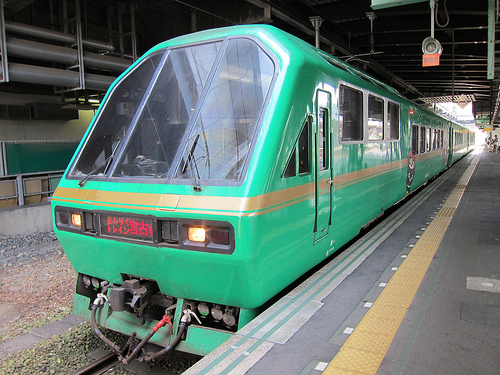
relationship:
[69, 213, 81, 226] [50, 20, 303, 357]
headlight on front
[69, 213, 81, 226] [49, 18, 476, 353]
headlight on train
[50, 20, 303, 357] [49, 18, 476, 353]
front of train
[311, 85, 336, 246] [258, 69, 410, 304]
door on side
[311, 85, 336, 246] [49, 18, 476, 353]
door on train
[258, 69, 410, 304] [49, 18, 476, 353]
side of train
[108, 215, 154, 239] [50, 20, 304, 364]
letters on front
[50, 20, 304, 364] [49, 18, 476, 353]
front of train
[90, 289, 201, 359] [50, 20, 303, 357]
wires on front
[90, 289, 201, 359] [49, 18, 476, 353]
wires on train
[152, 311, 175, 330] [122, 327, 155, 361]
grip on tube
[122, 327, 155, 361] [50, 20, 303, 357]
tube on front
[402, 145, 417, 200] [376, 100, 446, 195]
design on side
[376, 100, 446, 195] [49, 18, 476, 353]
side of train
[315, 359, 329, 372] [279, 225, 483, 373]
square on platform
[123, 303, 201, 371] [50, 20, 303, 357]
hoses on front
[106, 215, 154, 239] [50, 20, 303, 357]
letters on front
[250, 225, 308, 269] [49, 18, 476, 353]
green color on train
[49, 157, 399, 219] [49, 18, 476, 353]
border around train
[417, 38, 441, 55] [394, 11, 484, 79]
flood light in ceiling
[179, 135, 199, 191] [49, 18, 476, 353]
wiper on train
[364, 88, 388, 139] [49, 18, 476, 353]
window on train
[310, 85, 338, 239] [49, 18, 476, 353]
door on train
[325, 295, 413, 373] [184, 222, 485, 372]
line on ground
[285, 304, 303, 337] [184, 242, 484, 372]
stripe on ground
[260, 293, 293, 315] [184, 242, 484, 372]
stripe on ground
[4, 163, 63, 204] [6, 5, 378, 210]
railing against wall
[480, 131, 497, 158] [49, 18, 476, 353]
people on train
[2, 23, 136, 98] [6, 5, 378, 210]
pipes on wall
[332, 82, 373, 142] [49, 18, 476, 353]
window on side of train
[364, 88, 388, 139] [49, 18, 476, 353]
window on side of train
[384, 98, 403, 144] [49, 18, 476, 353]
window on side of train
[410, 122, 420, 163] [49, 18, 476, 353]
window on side of train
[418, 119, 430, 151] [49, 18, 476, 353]
window on side of train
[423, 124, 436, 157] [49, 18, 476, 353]
window on side of train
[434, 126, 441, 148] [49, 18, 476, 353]
window on side of train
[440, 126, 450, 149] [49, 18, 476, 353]
window on side of train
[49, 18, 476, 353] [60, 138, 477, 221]
train with stripe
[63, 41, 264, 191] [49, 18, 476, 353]
window of train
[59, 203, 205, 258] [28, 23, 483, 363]
headlight of train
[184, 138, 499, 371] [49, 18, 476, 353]
platform near train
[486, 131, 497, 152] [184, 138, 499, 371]
people on platform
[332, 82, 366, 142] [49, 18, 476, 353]
window on side of train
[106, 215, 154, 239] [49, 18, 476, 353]
letters on train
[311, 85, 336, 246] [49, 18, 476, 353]
door on side of train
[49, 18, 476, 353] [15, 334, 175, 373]
train moving down tracks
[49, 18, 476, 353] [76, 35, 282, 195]
train has windows